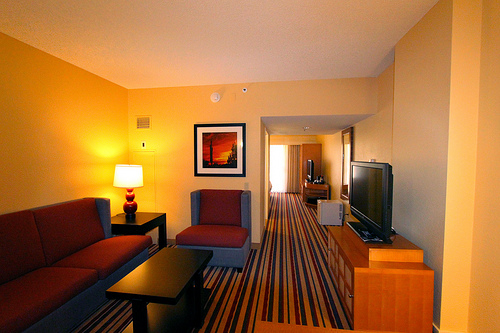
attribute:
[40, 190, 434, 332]
flooring — carpet, striped, red, blue, tan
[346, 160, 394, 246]
television set — flat screen, wide screen, off, black, plastic, flat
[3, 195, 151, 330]
sofa — red, grey, modern, blue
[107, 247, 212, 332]
coffee table — black, wooden, retangular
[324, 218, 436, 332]
dresser drawer — wooden, honey brown, brown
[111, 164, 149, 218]
lamp — red, providing light, stacked, circular, turned on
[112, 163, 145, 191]
lampshade — white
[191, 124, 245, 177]
catus photograph — framed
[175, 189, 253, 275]
chair — red, grey, modern, gray, blue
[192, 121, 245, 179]
frame — black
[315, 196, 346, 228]
fridge — white, small, square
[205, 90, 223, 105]
smoke detector — white, plastic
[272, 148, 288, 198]
window — in next room, large, backlit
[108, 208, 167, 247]
side table — black